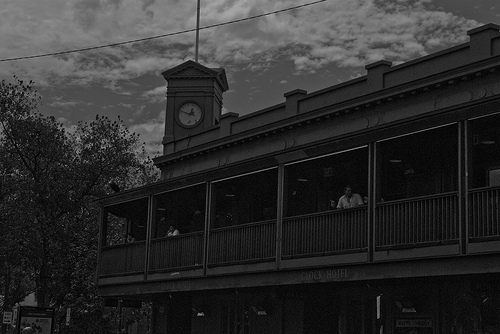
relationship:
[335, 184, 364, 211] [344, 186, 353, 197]
man has face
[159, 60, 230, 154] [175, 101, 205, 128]
tower has clock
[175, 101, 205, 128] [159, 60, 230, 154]
clock on tower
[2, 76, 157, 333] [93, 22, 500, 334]
trees next to building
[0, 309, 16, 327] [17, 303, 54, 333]
advertisement next to sign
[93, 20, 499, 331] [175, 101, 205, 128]
building has clock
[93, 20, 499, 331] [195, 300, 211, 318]
building has light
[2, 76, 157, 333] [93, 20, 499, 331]
trees near building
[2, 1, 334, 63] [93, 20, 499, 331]
wire over building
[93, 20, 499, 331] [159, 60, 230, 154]
building with tower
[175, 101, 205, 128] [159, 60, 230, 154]
clock has tower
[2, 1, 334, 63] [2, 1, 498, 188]
wire in sky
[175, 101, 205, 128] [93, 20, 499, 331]
clock on building